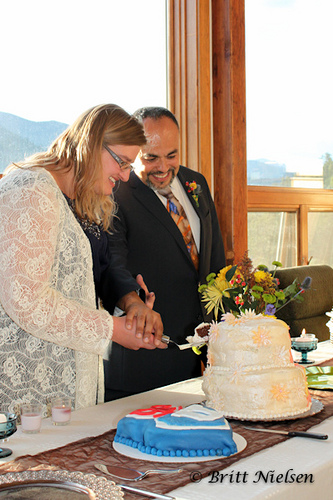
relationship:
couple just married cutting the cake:
[2, 104, 222, 414] [116, 288, 312, 419]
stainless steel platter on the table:
[0, 467, 124, 499] [2, 341, 333, 499]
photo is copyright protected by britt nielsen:
[2, 0, 333, 499] [191, 471, 315, 485]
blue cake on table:
[113, 405, 244, 463] [2, 341, 333, 499]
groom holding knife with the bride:
[133, 106, 226, 395] [1, 104, 145, 414]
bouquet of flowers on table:
[196, 257, 311, 326] [2, 341, 333, 499]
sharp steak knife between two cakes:
[242, 425, 326, 440] [113, 405, 244, 463]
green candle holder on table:
[291, 329, 318, 363] [2, 341, 333, 499]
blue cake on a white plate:
[113, 405, 244, 463] [113, 434, 249, 466]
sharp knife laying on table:
[242, 425, 326, 440] [2, 341, 333, 499]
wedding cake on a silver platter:
[203, 314, 311, 419] [224, 393, 323, 423]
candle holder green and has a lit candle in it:
[292, 337, 317, 361] [297, 327, 309, 341]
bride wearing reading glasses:
[1, 104, 145, 414] [104, 141, 135, 171]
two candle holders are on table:
[21, 405, 42, 435] [2, 341, 333, 499]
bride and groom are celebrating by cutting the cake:
[2, 104, 222, 414] [116, 288, 312, 419]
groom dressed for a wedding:
[133, 106, 226, 395] [2, 0, 333, 499]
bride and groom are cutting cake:
[2, 104, 222, 414] [203, 314, 311, 419]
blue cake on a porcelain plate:
[113, 405, 244, 463] [113, 434, 249, 466]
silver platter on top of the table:
[0, 467, 124, 499] [2, 341, 333, 499]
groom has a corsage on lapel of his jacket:
[133, 106, 226, 395] [183, 178, 204, 207]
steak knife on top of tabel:
[242, 425, 326, 440] [2, 341, 333, 499]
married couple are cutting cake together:
[2, 104, 222, 414] [203, 314, 311, 419]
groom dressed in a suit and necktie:
[133, 106, 226, 395] [157, 187, 201, 267]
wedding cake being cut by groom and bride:
[203, 314, 311, 419] [2, 104, 222, 414]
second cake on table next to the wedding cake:
[113, 405, 244, 463] [203, 314, 311, 419]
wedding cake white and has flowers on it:
[203, 314, 311, 419] [240, 309, 256, 320]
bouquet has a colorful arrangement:
[196, 257, 311, 326] [196, 249, 313, 313]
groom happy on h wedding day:
[133, 106, 226, 395] [2, 0, 333, 499]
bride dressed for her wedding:
[1, 104, 145, 414] [2, 0, 333, 499]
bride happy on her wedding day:
[1, 104, 145, 414] [2, 0, 333, 499]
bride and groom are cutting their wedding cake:
[2, 104, 222, 414] [203, 314, 311, 419]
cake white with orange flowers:
[203, 314, 311, 419] [252, 329, 273, 347]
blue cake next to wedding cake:
[113, 405, 244, 463] [203, 314, 311, 419]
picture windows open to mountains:
[2, 0, 333, 187] [1, 95, 332, 188]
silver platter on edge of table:
[0, 467, 124, 499] [2, 341, 333, 499]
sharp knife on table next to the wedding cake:
[242, 425, 326, 440] [203, 314, 311, 419]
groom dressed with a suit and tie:
[133, 106, 226, 395] [101, 165, 225, 400]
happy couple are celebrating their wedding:
[2, 104, 222, 414] [2, 0, 333, 499]